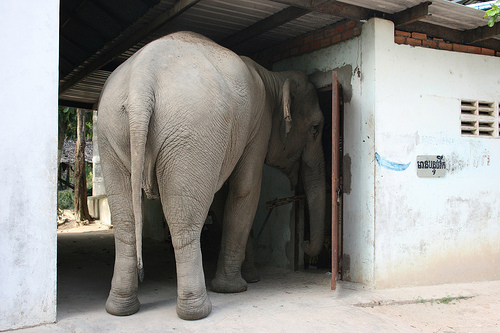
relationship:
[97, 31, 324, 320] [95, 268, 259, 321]
elephant has feet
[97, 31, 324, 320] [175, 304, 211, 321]
elephant has foot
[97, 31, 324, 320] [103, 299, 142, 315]
elephant has foot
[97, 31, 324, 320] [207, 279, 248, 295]
elephant has foot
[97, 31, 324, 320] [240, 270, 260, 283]
elephant has foot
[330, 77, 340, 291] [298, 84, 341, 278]
door in doorway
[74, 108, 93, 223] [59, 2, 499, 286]
tree behind building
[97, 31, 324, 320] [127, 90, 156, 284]
elephant has tail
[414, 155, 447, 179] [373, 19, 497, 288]
sign on wall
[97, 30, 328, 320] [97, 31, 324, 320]
skin on elephant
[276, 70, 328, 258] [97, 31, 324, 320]
head of elephant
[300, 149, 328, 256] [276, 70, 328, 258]
trunk on head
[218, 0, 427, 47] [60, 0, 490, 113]
frame of ceiling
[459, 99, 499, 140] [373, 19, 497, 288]
vents in wall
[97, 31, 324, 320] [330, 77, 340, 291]
elephant looking in door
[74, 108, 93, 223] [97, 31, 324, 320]
tree behind elephant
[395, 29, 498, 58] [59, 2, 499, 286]
bricks on building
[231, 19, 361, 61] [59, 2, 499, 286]
bricks on building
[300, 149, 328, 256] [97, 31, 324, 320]
trunk on elephant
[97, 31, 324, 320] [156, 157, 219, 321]
elephant has leg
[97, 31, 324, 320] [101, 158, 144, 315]
elephant has leg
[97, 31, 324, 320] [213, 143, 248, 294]
elephant has leg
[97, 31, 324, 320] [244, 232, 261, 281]
elephant has leg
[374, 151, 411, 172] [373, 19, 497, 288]
paint on wall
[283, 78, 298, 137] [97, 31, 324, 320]
ear on elephant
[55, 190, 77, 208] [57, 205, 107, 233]
weeds in ground